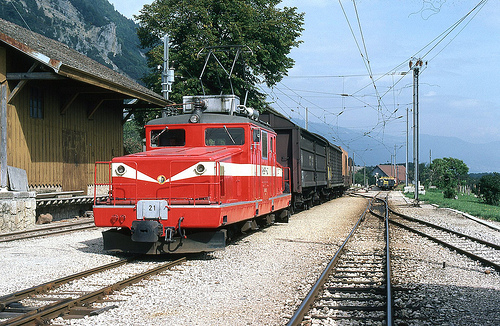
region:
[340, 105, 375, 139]
white clouds in blue sky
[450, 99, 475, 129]
white clouds in blue sky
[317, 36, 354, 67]
white clouds in blue sky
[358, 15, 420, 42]
white clouds in blue sky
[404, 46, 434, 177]
gray light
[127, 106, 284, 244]
red train engine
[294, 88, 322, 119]
white clouds in blue sky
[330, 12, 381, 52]
white clouds in blue sky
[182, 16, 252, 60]
green leaves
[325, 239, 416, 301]
gray metal train tracks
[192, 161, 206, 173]
Front light of train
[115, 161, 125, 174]
Right front train light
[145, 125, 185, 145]
Right front train window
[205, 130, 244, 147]
Left front train window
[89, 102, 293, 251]
The front of the train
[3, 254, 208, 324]
A pair of tracks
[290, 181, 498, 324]
train tracks crossing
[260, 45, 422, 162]
Mesh of wires overhead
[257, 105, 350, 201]
Train rear cargo unit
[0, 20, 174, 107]
The roof of a building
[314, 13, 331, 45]
white clouds in blue sky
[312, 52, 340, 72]
white clouds in blue sky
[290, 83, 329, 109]
white clouds in blue sky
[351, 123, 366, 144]
white clouds in blue sky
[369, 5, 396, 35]
white clouds in blue sky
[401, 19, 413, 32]
white clouds in blue sky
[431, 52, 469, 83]
white clouds in blue sky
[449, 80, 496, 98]
white clouds in blue sky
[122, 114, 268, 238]
red train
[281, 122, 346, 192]
black train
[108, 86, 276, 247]
red and white train engine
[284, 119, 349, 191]
black train cargo cars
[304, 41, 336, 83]
white clouds in blue sky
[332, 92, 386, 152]
white clouds in blue sky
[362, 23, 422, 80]
white clouds in blue sky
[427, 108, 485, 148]
white clouds in blue sky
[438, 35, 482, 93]
white clouds in blue sky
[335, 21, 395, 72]
white clouds in blue sky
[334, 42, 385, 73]
white clouds in blue sky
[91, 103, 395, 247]
large train on train tracks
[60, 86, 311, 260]
large red portion of train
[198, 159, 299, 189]
white stripe on side of train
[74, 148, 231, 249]
front safety bumper on train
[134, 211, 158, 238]
black attachment on front of train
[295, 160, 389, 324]
long steel train tracks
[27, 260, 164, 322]
white little rocks on train tracks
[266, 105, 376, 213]
large black train cars on track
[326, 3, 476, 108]
power lines by train tracks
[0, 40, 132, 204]
small train waiting area